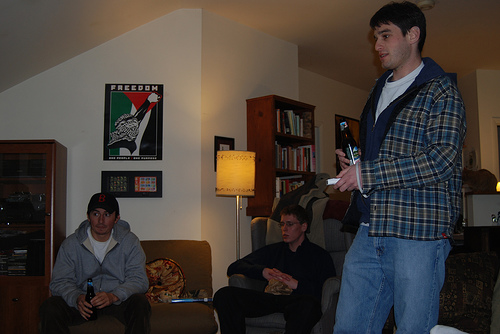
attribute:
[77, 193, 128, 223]
cap — ball, covering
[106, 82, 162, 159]
art decor — affixed